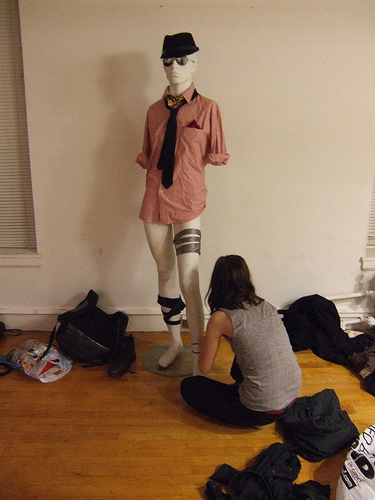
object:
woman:
[180, 255, 302, 427]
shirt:
[216, 298, 301, 410]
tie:
[156, 88, 199, 189]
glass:
[176, 57, 186, 65]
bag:
[336, 424, 375, 498]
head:
[210, 254, 251, 298]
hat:
[161, 31, 199, 59]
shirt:
[135, 83, 228, 223]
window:
[0, 0, 39, 251]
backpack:
[55, 288, 129, 365]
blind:
[0, 0, 38, 248]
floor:
[0, 321, 374, 497]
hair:
[204, 254, 265, 316]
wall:
[0, 0, 375, 332]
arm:
[197, 316, 219, 373]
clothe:
[275, 387, 359, 461]